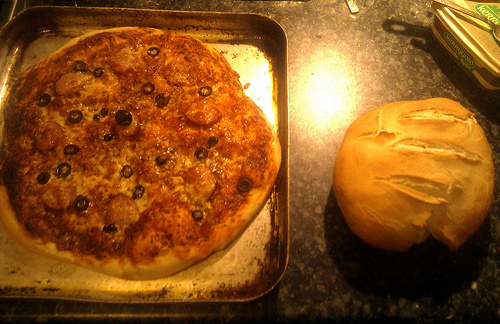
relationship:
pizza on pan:
[0, 26, 281, 280] [3, 5, 291, 304]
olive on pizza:
[92, 65, 106, 78] [0, 26, 281, 280]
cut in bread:
[375, 171, 462, 206] [333, 97, 495, 252]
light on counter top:
[282, 43, 364, 140] [2, 1, 498, 323]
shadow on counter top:
[379, 14, 496, 126] [2, 1, 498, 323]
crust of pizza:
[3, 5, 291, 304] [0, 26, 281, 280]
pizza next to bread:
[0, 26, 281, 280] [333, 97, 495, 252]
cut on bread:
[375, 171, 462, 206] [333, 97, 495, 252]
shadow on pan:
[2, 235, 73, 280] [3, 5, 291, 304]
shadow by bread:
[323, 188, 491, 306] [333, 97, 495, 252]